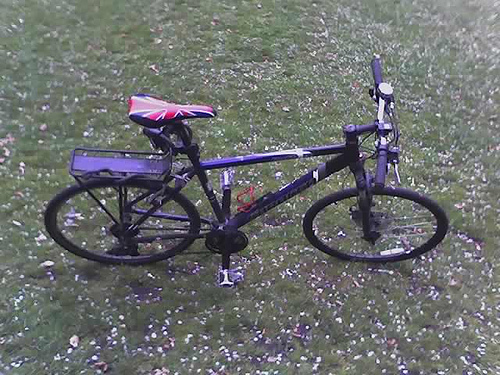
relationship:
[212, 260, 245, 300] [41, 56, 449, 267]
pedal on bike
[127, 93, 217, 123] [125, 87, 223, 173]
flag on seat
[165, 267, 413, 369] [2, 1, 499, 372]
debris on ground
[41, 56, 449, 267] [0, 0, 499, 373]
bike on lawn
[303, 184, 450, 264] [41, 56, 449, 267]
tire on bike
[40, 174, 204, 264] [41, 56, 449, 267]
rear tire on bike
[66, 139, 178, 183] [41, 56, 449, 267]
shelf on bike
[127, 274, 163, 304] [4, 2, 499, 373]
dirt patch on grass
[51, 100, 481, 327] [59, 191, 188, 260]
bike has spokes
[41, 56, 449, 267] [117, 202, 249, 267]
bike has chain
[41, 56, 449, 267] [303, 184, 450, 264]
bike has tire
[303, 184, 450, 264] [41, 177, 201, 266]
tire has rear tire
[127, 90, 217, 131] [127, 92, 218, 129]
bike seat has bike seat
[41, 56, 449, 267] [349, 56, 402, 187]
bike has handlebars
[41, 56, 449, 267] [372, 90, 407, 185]
bike has brakes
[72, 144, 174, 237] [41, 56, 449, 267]
basket on bike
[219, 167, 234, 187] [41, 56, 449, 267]
pedal on bike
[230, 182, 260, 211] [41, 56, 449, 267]
holder on bike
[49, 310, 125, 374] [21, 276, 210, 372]
pebbles in grass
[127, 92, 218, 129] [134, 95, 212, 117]
bike seat has union-jack design